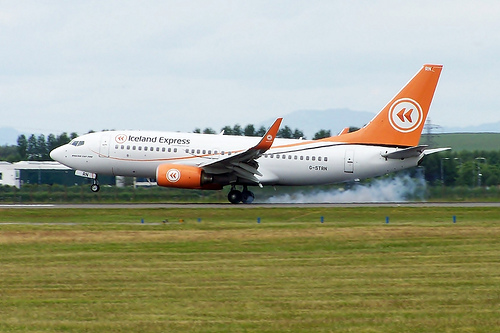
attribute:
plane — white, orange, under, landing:
[23, 87, 360, 192]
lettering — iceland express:
[119, 124, 204, 154]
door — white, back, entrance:
[92, 131, 121, 167]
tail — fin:
[333, 47, 463, 196]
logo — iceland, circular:
[122, 134, 191, 154]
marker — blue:
[360, 197, 404, 247]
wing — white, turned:
[210, 135, 252, 173]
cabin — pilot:
[56, 113, 104, 167]